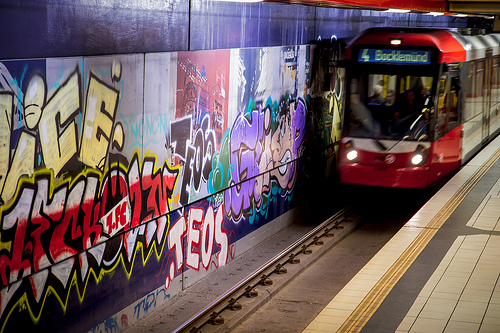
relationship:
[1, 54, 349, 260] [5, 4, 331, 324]
graffiti on wall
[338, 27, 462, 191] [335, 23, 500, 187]
front of train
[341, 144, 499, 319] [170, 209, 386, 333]
yellow line along track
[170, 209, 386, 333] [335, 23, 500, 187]
track for train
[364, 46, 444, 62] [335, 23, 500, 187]
sign on train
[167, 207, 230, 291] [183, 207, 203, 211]
white letters outlined in red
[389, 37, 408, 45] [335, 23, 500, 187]
light on train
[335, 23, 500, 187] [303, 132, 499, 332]
train approaches platform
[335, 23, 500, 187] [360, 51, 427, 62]
train posts destination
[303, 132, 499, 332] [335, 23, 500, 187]
platform for train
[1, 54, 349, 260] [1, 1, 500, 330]
graffiti in station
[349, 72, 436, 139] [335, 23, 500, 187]
windshield on train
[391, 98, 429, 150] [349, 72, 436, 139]
wiper on windshield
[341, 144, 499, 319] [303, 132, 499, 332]
yellow line on platform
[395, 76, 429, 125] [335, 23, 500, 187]
engineer of train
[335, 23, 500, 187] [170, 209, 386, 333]
train on track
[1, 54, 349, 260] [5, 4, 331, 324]
graffiti painted on wall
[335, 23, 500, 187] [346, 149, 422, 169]
train has headlights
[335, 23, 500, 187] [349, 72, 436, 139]
train has a windshield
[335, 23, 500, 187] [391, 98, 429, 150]
train has a wiper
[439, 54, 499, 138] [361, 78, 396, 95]
windows for passengers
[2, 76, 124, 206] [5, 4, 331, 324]
lice written on wall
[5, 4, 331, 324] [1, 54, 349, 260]
wall covered in graffiti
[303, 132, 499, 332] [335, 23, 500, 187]
yellow line by train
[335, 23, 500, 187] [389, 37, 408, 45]
train has a light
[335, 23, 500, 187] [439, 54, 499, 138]
train has windows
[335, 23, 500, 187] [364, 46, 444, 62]
train has a sign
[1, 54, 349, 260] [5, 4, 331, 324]
graffiti on a wall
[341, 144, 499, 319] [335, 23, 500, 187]
yellow line by train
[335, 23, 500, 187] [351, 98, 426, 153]
train has wipers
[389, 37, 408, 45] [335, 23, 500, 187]
light above on train